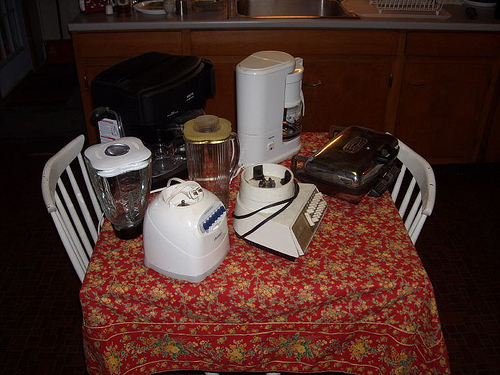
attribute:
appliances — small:
[86, 50, 404, 284]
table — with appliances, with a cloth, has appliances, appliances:
[89, 127, 430, 320]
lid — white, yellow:
[190, 117, 223, 144]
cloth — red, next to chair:
[108, 134, 417, 309]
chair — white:
[39, 126, 435, 231]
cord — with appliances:
[232, 185, 313, 246]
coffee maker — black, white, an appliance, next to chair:
[233, 49, 308, 168]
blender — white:
[184, 117, 232, 203]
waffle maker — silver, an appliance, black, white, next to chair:
[292, 118, 401, 199]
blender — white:
[85, 145, 151, 235]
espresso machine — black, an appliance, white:
[91, 44, 214, 183]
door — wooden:
[69, 32, 493, 177]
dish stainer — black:
[371, 3, 447, 20]